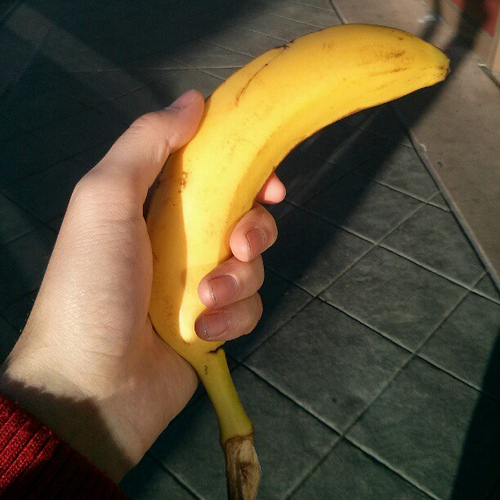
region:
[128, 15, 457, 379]
ripe banana in hand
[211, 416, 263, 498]
stem at end of banana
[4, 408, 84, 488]
red sweater on wrist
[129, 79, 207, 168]
thumb on edge of banana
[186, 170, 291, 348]
four fingers under banana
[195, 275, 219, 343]
dirty fingernails on hand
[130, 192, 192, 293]
shadow of hand on banana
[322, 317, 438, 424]
gray tiles on floor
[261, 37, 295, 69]
discoloration on yellow banana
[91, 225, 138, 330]
creases in hand flesh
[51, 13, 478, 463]
a person holding a fruit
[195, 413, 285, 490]
a torn fruit stem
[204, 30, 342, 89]
black marks on yellow peel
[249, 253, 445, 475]
a grey tile floor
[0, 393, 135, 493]
a red knit sleeve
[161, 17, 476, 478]
a ripe, unpeeled banana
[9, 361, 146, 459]
a shadow on a wrist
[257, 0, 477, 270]
a shadow on the ground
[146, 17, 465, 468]
a bright yellow fruit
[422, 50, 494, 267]
cement ground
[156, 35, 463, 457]
yellow and brown banana being held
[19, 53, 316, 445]
hand holding yellow banana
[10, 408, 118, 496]
sleeve of person wearing red sweater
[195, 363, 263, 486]
green spot on banana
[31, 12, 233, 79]
gray street pavement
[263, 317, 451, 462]
gray street pavement squares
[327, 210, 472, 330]
gray street pavement squares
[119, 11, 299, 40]
gray street pavement squares in shadows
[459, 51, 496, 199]
tan street pavement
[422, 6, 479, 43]
black shadows on street pavement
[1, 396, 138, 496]
The person is wearing a red sweater.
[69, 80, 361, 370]
The hand is holding a banana.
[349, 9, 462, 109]
The banana skin is intact.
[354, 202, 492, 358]
The floor is made of concrete tiles.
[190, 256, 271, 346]
The man's nails are dirty.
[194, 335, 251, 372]
The banana peel is cracked.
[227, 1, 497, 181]
There is light coming from behind, stretching the person shadow.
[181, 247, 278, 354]
The person's nails are short.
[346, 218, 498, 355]
The floor has two colors: gray and tan.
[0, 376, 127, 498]
The person is wearing a warm sweater.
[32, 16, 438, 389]
banana in person's hand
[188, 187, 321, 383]
person with dirty nails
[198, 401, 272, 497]
end of banana stem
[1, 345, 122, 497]
person's red sweater cuff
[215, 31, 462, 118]
banana with brown discoloration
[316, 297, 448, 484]
grey tiles on floor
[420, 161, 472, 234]
crevices on tile floor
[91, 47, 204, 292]
person thumb on hand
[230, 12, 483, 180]
banana pointed like gun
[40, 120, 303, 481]
hand gripping yellow banana